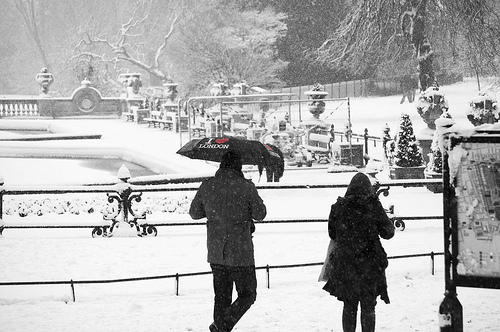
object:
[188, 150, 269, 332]
man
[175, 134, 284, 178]
umbrella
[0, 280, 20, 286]
rails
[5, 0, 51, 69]
trees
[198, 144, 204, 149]
words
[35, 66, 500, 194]
sculpture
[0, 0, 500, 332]
snow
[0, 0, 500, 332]
picture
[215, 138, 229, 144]
heart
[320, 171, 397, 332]
person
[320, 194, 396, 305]
jacket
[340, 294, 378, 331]
pants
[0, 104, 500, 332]
ground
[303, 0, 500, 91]
tree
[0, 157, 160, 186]
water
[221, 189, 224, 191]
clothes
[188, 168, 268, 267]
coat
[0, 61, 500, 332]
park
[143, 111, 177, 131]
bench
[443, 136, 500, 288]
map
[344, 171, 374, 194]
hood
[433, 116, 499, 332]
sign